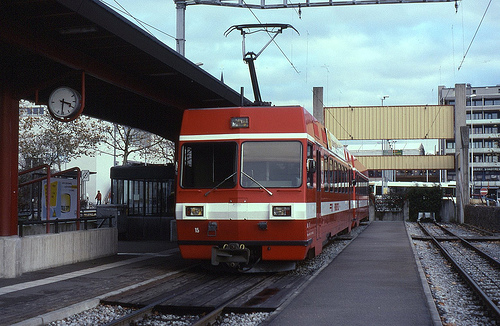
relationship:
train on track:
[170, 106, 371, 277] [107, 274, 268, 324]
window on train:
[332, 161, 339, 190] [170, 106, 371, 277]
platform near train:
[0, 233, 175, 325] [170, 106, 371, 277]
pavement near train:
[264, 212, 435, 325] [170, 106, 371, 277]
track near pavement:
[107, 274, 268, 324] [264, 212, 435, 325]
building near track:
[325, 106, 456, 217] [107, 274, 268, 324]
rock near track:
[115, 302, 124, 310] [107, 274, 268, 324]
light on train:
[185, 206, 203, 218] [170, 106, 371, 277]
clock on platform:
[48, 85, 80, 122] [0, 233, 175, 325]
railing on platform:
[2, 215, 118, 236] [0, 233, 175, 325]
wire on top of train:
[243, 0, 260, 23] [170, 106, 371, 277]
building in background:
[325, 106, 456, 217] [0, 0, 500, 244]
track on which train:
[107, 274, 268, 324] [170, 106, 371, 277]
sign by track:
[39, 177, 80, 222] [107, 274, 268, 324]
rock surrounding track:
[115, 302, 124, 310] [107, 274, 268, 324]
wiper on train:
[205, 171, 239, 196] [170, 106, 371, 277]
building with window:
[438, 86, 500, 207] [485, 101, 495, 105]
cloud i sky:
[255, 56, 292, 76] [100, 3, 499, 115]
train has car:
[170, 106, 371, 277] [351, 157, 376, 234]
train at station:
[170, 106, 371, 277] [0, 20, 445, 324]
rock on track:
[115, 302, 124, 310] [107, 274, 268, 324]